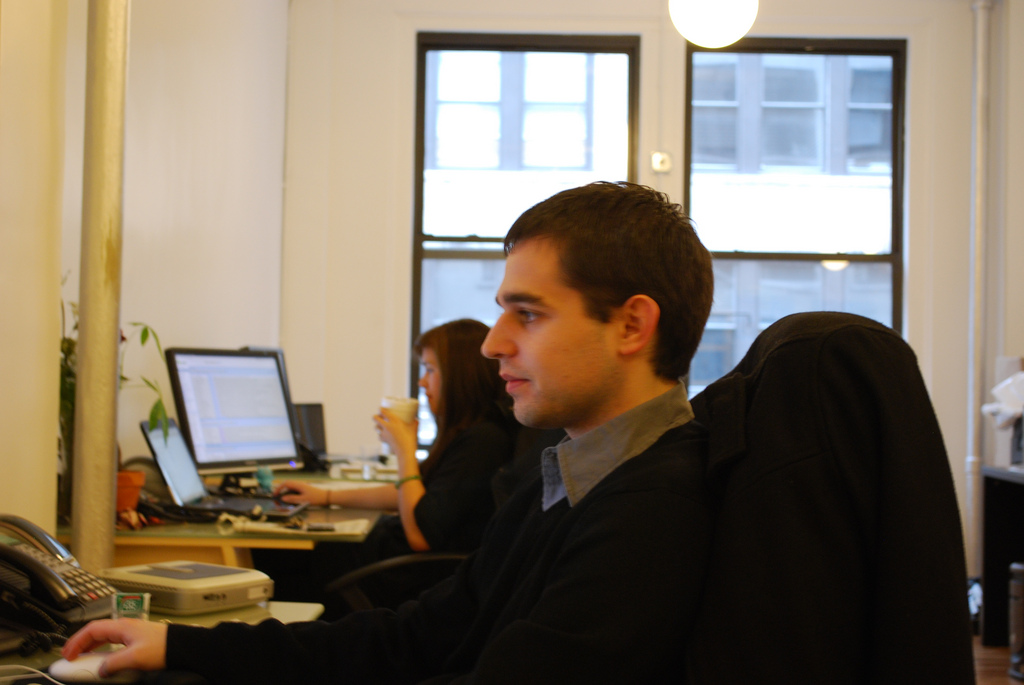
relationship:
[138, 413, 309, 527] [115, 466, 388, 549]
laptop on table